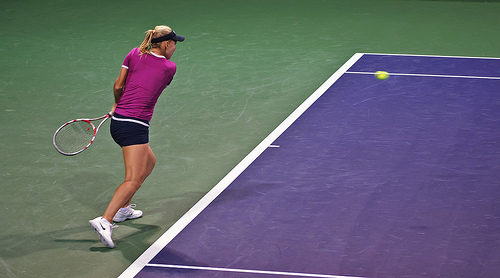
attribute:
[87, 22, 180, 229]
lady — playing, preparing, ready, blond, young, strinking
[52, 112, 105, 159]
racket — red, grey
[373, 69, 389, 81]
ball — yellow, incoming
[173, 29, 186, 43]
visor — black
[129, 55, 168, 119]
shirt — purple, pink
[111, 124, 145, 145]
short — black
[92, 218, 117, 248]
shoes — white, nike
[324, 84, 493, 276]
court — blue, pulpe, purple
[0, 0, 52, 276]
ground — green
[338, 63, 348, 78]
line — white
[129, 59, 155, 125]
t-shirt — colored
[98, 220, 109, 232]
one — nike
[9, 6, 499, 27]
court — green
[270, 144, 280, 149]
line — small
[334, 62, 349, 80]
edge — bold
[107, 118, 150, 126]
edge — white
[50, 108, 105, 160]
racquet — stripped